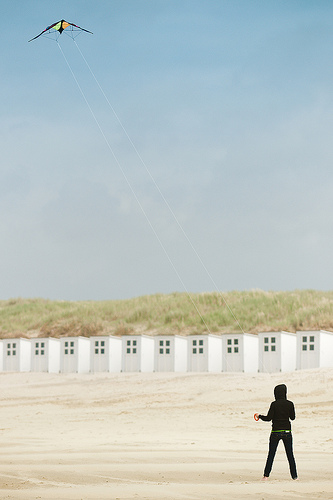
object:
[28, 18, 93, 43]
kite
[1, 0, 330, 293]
sky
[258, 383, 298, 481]
woman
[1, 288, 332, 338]
grass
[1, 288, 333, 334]
hill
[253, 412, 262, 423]
handle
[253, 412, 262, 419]
hand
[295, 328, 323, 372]
building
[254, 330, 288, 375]
building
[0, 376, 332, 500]
beach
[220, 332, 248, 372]
building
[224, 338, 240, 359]
window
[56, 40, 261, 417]
string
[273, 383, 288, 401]
head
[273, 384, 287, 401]
hood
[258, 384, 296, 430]
jacket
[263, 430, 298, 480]
pants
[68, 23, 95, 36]
wing